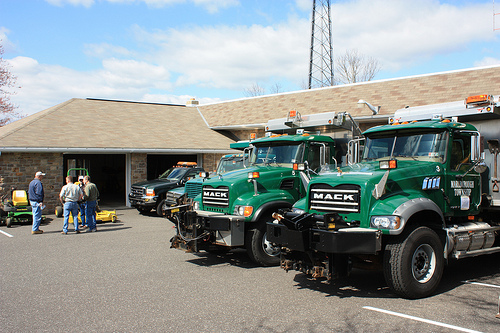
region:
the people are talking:
[22, 164, 114, 253]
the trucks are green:
[167, 127, 437, 294]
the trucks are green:
[174, 139, 258, 222]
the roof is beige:
[53, 95, 150, 146]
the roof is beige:
[224, 104, 264, 121]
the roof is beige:
[294, 89, 358, 127]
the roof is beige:
[390, 71, 459, 121]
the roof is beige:
[175, 127, 222, 170]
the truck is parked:
[315, 97, 466, 309]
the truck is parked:
[201, 118, 331, 253]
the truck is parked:
[165, 152, 231, 219]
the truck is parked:
[109, 143, 223, 210]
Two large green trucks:
[158, 94, 498, 278]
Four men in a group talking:
[24, 163, 103, 252]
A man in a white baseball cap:
[28, 166, 55, 241]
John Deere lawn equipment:
[1, 180, 36, 231]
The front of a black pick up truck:
[126, 153, 209, 221]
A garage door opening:
[59, 148, 134, 216]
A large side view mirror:
[456, 119, 489, 180]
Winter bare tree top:
[328, 38, 388, 103]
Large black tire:
[385, 222, 449, 299]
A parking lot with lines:
[2, 202, 495, 332]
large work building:
[8, 61, 495, 229]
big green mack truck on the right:
[265, 92, 498, 312]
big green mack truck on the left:
[174, 94, 351, 291]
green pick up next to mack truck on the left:
[166, 145, 271, 215]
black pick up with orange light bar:
[129, 154, 208, 218]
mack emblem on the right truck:
[301, 177, 359, 214]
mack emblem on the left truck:
[197, 177, 233, 215]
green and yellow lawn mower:
[1, 184, 35, 229]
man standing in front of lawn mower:
[25, 167, 47, 230]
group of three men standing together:
[54, 168, 104, 236]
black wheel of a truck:
[382, 223, 449, 300]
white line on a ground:
[357, 301, 498, 332]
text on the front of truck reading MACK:
[309, 191, 355, 201]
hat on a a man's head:
[33, 168, 47, 177]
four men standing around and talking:
[27, 166, 103, 236]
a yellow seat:
[11, 187, 29, 206]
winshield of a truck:
[364, 133, 443, 161]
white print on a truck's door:
[447, 179, 477, 196]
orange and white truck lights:
[377, 158, 400, 169]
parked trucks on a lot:
[125, 90, 497, 301]